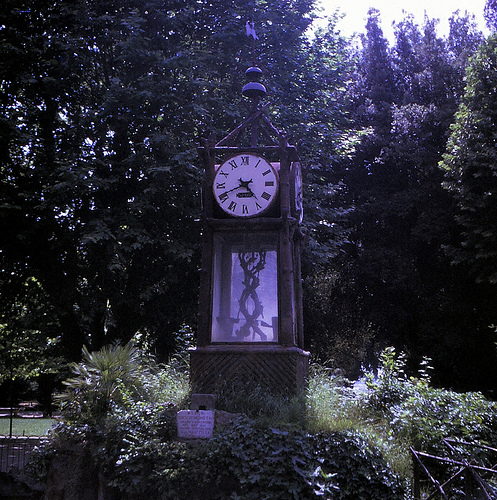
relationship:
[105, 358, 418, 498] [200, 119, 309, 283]
bush around clock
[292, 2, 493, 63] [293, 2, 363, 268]
sunlight on tree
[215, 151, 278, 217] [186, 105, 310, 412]
clock on tower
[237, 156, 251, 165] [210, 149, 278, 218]
number on clock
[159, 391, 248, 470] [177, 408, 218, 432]
sign has engraving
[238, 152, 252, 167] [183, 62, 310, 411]
number on clock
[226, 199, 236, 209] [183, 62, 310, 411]
roman numeral on clock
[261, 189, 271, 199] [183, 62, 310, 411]
roman numeral on clock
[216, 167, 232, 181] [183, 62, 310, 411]
number on clock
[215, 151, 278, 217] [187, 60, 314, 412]
clock on tower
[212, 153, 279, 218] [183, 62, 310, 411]
face on clock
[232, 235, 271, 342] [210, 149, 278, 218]
pattern inside clock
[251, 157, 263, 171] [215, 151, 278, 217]
number on clock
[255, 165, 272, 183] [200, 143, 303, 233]
number on clock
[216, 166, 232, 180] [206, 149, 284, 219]
number on clock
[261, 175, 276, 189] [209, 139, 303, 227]
number on clock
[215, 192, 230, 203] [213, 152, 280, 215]
number on clock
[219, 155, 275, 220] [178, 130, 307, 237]
number on clock